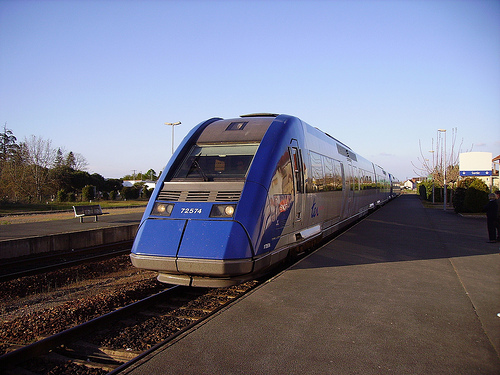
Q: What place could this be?
A: It is a pavement.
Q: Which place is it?
A: It is a pavement.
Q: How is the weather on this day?
A: It is clear.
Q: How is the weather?
A: It is clear.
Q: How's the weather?
A: It is clear.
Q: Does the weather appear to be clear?
A: Yes, it is clear.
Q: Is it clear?
A: Yes, it is clear.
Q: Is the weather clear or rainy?
A: It is clear.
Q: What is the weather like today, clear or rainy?
A: It is clear.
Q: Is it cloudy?
A: No, it is clear.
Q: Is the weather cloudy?
A: No, it is clear.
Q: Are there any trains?
A: Yes, there is a train.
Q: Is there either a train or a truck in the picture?
A: Yes, there is a train.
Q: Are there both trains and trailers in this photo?
A: No, there is a train but no trailers.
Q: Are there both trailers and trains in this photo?
A: No, there is a train but no trailers.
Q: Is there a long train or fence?
A: Yes, there is a long train.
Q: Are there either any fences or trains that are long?
A: Yes, the train is long.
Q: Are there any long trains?
A: Yes, there is a long train.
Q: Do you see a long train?
A: Yes, there is a long train.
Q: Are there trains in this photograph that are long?
A: Yes, there is a train that is long.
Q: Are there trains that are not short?
A: Yes, there is a long train.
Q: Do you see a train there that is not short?
A: Yes, there is a long train.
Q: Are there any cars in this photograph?
A: No, there are no cars.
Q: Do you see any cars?
A: No, there are no cars.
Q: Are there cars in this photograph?
A: No, there are no cars.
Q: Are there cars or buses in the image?
A: No, there are no cars or buses.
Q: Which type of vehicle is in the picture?
A: The vehicle is a train.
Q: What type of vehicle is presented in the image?
A: The vehicle is a train.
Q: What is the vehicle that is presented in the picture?
A: The vehicle is a train.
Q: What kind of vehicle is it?
A: The vehicle is a train.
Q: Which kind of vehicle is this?
A: This is a train.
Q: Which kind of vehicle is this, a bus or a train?
A: This is a train.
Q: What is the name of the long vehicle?
A: The vehicle is a train.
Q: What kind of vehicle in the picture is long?
A: The vehicle is a train.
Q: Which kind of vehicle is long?
A: The vehicle is a train.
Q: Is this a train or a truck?
A: This is a train.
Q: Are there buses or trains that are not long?
A: No, there is a train but it is long.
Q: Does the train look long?
A: Yes, the train is long.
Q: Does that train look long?
A: Yes, the train is long.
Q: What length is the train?
A: The train is long.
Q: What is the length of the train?
A: The train is long.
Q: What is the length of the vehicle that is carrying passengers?
A: The train is long.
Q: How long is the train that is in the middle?
A: The train is long.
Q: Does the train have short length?
A: No, the train is long.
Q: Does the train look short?
A: No, the train is long.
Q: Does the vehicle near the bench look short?
A: No, the train is long.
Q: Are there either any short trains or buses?
A: No, there is a train but it is long.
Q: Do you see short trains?
A: No, there is a train but it is long.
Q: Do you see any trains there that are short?
A: No, there is a train but it is long.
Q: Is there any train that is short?
A: No, there is a train but it is long.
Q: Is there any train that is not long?
A: No, there is a train but it is long.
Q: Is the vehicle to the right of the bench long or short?
A: The train is long.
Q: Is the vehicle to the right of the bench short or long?
A: The train is long.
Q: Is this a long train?
A: Yes, this is a long train.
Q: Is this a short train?
A: No, this is a long train.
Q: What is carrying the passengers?
A: The train is carrying the passengers.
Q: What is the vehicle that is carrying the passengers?
A: The vehicle is a train.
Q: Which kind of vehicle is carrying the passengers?
A: The vehicle is a train.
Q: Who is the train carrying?
A: The train is carrying passengers.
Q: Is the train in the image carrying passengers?
A: Yes, the train is carrying passengers.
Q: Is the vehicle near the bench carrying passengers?
A: Yes, the train is carrying passengers.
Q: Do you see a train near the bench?
A: Yes, there is a train near the bench.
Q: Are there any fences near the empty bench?
A: No, there is a train near the bench.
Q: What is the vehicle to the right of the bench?
A: The vehicle is a train.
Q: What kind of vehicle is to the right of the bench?
A: The vehicle is a train.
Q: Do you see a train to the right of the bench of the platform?
A: Yes, there is a train to the right of the bench.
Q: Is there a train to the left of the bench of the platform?
A: No, the train is to the right of the bench.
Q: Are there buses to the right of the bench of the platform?
A: No, there is a train to the right of the bench.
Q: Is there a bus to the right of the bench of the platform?
A: No, there is a train to the right of the bench.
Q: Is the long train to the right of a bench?
A: Yes, the train is to the right of a bench.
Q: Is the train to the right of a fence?
A: No, the train is to the right of a bench.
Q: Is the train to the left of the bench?
A: No, the train is to the right of the bench.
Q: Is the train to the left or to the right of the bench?
A: The train is to the right of the bench.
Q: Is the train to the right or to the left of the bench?
A: The train is to the right of the bench.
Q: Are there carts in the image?
A: No, there are no carts.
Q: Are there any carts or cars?
A: No, there are no carts or cars.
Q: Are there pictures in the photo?
A: No, there are no pictures.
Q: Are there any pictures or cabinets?
A: No, there are no pictures or cabinets.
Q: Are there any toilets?
A: No, there are no toilets.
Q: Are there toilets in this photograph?
A: No, there are no toilets.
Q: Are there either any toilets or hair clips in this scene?
A: No, there are no toilets or hair clips.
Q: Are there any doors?
A: Yes, there is a door.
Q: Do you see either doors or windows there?
A: Yes, there is a door.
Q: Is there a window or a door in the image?
A: Yes, there is a door.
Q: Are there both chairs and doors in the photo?
A: No, there is a door but no chairs.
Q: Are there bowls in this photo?
A: No, there are no bowls.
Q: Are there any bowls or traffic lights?
A: No, there are no bowls or traffic lights.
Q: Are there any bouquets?
A: No, there are no bouquets.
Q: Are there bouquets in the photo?
A: No, there are no bouquets.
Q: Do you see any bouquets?
A: No, there are no bouquets.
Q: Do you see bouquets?
A: No, there are no bouquets.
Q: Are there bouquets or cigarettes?
A: No, there are no bouquets or cigarettes.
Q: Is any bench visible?
A: Yes, there is a bench.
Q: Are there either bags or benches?
A: Yes, there is a bench.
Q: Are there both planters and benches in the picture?
A: No, there is a bench but no planters.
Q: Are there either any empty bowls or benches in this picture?
A: Yes, there is an empty bench.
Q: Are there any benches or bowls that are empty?
A: Yes, the bench is empty.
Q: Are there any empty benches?
A: Yes, there is an empty bench.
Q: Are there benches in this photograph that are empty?
A: Yes, there is a bench that is empty.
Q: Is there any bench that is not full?
A: Yes, there is a empty bench.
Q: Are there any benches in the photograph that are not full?
A: Yes, there is a empty bench.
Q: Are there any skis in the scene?
A: No, there are no skis.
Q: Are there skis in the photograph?
A: No, there are no skis.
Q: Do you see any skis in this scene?
A: No, there are no skis.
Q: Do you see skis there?
A: No, there are no skis.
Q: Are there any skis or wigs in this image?
A: No, there are no skis or wigs.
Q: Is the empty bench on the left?
A: Yes, the bench is on the left of the image.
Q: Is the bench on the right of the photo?
A: No, the bench is on the left of the image.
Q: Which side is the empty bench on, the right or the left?
A: The bench is on the left of the image.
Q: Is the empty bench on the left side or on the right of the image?
A: The bench is on the left of the image.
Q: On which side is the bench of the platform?
A: The bench is on the left of the image.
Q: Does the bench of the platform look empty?
A: Yes, the bench is empty.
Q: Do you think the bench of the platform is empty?
A: Yes, the bench is empty.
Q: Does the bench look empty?
A: Yes, the bench is empty.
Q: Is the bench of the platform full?
A: No, the bench is empty.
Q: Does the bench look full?
A: No, the bench is empty.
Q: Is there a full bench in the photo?
A: No, there is a bench but it is empty.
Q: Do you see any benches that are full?
A: No, there is a bench but it is empty.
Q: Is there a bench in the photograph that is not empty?
A: No, there is a bench but it is empty.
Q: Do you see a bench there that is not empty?
A: No, there is a bench but it is empty.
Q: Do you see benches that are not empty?
A: No, there is a bench but it is empty.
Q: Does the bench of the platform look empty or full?
A: The bench is empty.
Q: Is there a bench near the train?
A: Yes, there is a bench near the train.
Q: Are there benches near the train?
A: Yes, there is a bench near the train.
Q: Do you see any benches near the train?
A: Yes, there is a bench near the train.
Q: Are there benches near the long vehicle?
A: Yes, there is a bench near the train.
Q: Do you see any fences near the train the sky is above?
A: No, there is a bench near the train.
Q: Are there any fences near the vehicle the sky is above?
A: No, there is a bench near the train.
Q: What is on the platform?
A: The bench is on the platform.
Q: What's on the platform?
A: The bench is on the platform.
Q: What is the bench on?
A: The bench is on the platform.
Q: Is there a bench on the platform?
A: Yes, there is a bench on the platform.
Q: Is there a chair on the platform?
A: No, there is a bench on the platform.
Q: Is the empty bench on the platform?
A: Yes, the bench is on the platform.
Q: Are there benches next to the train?
A: Yes, there is a bench next to the train.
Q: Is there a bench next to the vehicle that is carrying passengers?
A: Yes, there is a bench next to the train.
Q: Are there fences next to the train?
A: No, there is a bench next to the train.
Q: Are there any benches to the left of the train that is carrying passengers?
A: Yes, there is a bench to the left of the train.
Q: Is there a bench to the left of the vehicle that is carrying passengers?
A: Yes, there is a bench to the left of the train.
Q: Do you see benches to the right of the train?
A: No, the bench is to the left of the train.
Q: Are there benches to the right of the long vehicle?
A: No, the bench is to the left of the train.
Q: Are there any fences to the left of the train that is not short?
A: No, there is a bench to the left of the train.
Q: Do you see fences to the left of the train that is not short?
A: No, there is a bench to the left of the train.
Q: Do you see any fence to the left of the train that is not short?
A: No, there is a bench to the left of the train.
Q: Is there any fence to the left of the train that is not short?
A: No, there is a bench to the left of the train.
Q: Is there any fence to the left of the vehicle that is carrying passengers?
A: No, there is a bench to the left of the train.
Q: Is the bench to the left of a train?
A: Yes, the bench is to the left of a train.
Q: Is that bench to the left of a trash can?
A: No, the bench is to the left of a train.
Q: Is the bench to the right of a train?
A: No, the bench is to the left of a train.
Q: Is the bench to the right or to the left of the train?
A: The bench is to the left of the train.